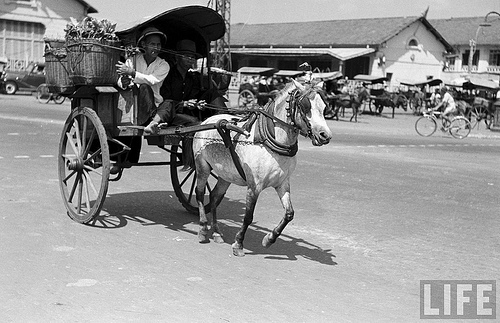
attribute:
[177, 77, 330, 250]
horse — white, trotting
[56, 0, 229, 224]
carriage — wooden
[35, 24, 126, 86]
basket — full, wicker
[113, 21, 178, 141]
man — shoeless, old, smoking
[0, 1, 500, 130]
carriages — covered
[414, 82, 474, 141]
person — riding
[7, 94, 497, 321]
road — paved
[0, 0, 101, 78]
building — tallest, white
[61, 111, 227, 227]
wheels — large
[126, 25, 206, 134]
men — riding, sitting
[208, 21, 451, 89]
building — long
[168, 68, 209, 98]
shirt — dark, black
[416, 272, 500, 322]
life — white, letters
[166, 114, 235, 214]
wheel — wooden